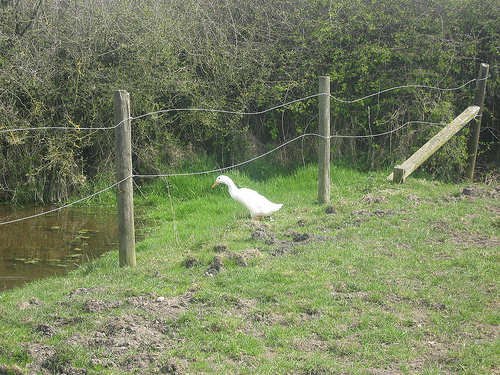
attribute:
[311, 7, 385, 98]
tree — green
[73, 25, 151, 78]
limbs — bare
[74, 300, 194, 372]
grass — brownish, dead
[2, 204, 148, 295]
water — murky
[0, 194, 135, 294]
dirty water — brown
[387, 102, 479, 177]
pole — fallen, wooden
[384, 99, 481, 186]
wood piece — broken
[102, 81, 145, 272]
fence pole — wooden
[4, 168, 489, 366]
grass — green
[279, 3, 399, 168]
limbs — leafy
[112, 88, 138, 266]
fence pole — wooden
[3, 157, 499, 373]
grass — bright, green